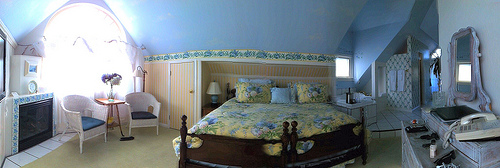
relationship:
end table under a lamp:
[200, 104, 222, 118] [206, 80, 222, 106]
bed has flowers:
[171, 79, 368, 167] [174, 82, 368, 154]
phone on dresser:
[443, 113, 499, 149] [402, 27, 499, 167]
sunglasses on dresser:
[435, 149, 457, 165] [402, 27, 499, 167]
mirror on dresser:
[450, 30, 479, 102] [402, 27, 499, 167]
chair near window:
[123, 91, 162, 138] [42, 3, 129, 102]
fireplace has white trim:
[18, 98, 54, 154] [12, 92, 61, 157]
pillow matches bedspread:
[233, 81, 275, 104] [173, 95, 371, 160]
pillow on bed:
[233, 81, 275, 104] [171, 79, 368, 167]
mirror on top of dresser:
[450, 30, 479, 102] [402, 27, 499, 167]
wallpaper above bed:
[140, 48, 335, 66] [171, 79, 368, 167]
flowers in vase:
[100, 71, 123, 103] [109, 89, 115, 104]